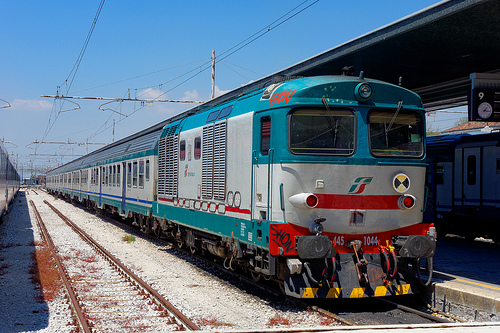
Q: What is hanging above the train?
A: Suspended power lines.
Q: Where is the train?
A: Next to the platform.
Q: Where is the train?
A: Tracks.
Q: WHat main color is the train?
A: Blue.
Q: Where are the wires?
A: Above train.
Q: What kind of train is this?
A: Passenger.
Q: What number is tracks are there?
A: 2.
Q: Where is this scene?
A: Train station.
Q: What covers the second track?
A: Gravel.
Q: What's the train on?
A: Tracks.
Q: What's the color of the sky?
A: Blue.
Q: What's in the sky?
A: Clouds.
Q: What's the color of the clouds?
A: White.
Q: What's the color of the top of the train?
A: Blue.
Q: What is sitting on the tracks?
A: A train.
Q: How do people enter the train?
A: The doors.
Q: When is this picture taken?
A: During the day.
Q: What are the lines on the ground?
A: Train tracks.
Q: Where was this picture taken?
A: Train station.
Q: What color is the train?
A: Blue and silver.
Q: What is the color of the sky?
A: Blue.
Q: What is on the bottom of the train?
A: The wheels.